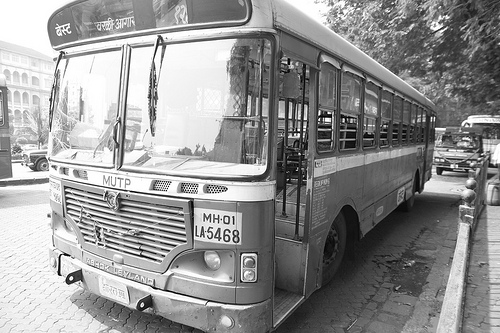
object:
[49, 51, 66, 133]
windshield wiper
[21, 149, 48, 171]
vehicle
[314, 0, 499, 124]
trees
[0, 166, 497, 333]
road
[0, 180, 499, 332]
brick road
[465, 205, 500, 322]
sidewalk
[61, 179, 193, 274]
grill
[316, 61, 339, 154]
window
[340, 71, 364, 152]
window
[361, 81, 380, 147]
window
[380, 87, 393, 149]
window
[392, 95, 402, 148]
window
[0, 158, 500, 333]
street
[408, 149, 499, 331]
side walk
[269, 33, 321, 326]
door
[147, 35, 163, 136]
windshield wipers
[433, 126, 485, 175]
van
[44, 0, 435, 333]
bus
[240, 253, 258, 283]
signal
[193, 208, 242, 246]
id number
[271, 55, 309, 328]
open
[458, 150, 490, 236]
fence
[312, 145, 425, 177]
stripe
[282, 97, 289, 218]
poles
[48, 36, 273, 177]
windshield